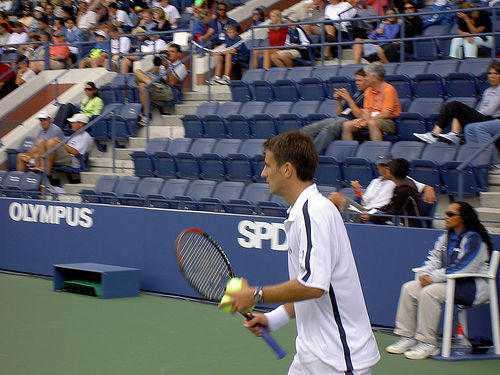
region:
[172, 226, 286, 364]
Blue handled tennis racket.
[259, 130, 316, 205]
face of a brown haired guy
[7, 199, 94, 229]
white writing that says OLYMPUS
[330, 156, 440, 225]
Two people sitting talking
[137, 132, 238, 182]
group of blue seats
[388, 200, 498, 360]
Long black haired person sitting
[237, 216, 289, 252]
SPD in white letters.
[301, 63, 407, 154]
Two people sitting together, one in orange shirt.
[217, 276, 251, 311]
Two tennis balls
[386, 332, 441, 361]
white sneakers that are being worn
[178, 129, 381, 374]
a tennis player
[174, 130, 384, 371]
a player holding at least two tennis balls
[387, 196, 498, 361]
a tennis official sitting on the court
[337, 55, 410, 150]
a spectator in an orange shirt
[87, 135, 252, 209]
empty seats at the tennis match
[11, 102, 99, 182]
men in white hats and shorts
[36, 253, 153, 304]
a small stand on the court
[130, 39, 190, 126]
a man with a camera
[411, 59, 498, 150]
a person with feet on the next row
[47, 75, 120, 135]
a person sitting alone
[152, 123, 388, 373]
man holding tennis racket and tennis balls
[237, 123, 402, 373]
man wearing white shirt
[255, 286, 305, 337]
white wrist band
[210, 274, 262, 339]
three ball in mans hand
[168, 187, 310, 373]
red and black tennis racket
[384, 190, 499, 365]
lady sitting on chair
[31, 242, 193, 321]
blue step stool on tennis court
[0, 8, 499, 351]
blue chairs in the audience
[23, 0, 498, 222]
people sitting and watching match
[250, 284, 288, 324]
man wearing watch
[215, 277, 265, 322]
Three tennis balls in the man's hand.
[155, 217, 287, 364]
Tennis racket in the player's hand.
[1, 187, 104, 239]
Olympus advertisement on blue wall.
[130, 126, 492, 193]
Empty row of blue seats.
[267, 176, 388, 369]
White shirt on the tennis player.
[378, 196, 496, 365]
Woman wearing sunglasses on the sideline.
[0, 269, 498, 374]
Green tennis court.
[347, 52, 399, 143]
Fan with grey hair and an orange shirt.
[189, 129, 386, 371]
Male tennis player wearing white.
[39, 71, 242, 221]
Stairway leading to the exit.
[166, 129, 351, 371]
this is a tennis player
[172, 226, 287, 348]
his hands are holding balls and racket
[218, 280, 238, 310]
the balls are green in color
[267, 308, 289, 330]
the hand has wrist band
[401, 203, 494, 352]
this man is sitted in a chair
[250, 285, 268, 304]
the player has wrist watch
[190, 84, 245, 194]
the seats are empty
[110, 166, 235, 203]
the seats are blue in color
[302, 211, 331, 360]
the man is wearing white t shirt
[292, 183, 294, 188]
the man is light skinned